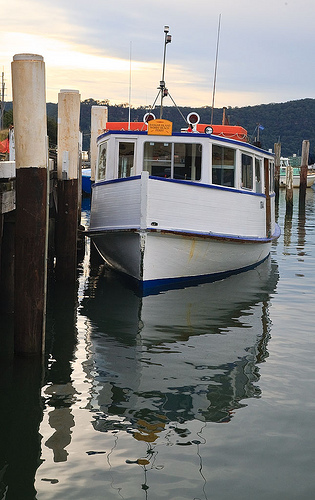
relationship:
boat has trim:
[85, 13, 281, 297] [92, 174, 274, 199]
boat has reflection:
[85, 13, 281, 297] [78, 261, 279, 426]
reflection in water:
[78, 261, 279, 426] [2, 183, 313, 496]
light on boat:
[143, 112, 155, 127] [85, 13, 281, 297]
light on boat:
[185, 111, 200, 126] [85, 13, 281, 297]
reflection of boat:
[78, 261, 281, 442] [85, 13, 281, 297]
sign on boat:
[147, 119, 172, 136] [73, 17, 293, 304]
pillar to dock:
[11, 53, 47, 353] [0, 54, 108, 355]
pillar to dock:
[54, 85, 79, 283] [0, 54, 108, 355]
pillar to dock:
[91, 102, 112, 182] [0, 54, 108, 355]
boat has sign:
[91, 21, 290, 295] [147, 119, 172, 136]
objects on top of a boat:
[105, 121, 248, 139] [85, 13, 281, 297]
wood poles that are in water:
[5, 39, 72, 226] [82, 267, 113, 285]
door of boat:
[264, 158, 273, 240] [85, 13, 281, 297]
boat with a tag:
[85, 13, 281, 297] [146, 119, 171, 135]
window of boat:
[139, 137, 206, 182] [85, 13, 281, 297]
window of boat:
[206, 141, 238, 188] [85, 13, 281, 297]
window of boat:
[115, 138, 137, 179] [85, 13, 281, 297]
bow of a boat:
[110, 152, 187, 311] [85, 13, 281, 297]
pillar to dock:
[56, 89, 81, 284] [1, 56, 100, 434]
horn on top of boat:
[135, 108, 161, 142] [46, 71, 284, 308]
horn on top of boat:
[185, 108, 203, 133] [46, 71, 284, 308]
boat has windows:
[85, 13, 281, 297] [97, 140, 274, 194]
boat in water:
[85, 13, 281, 297] [0, 195, 304, 485]